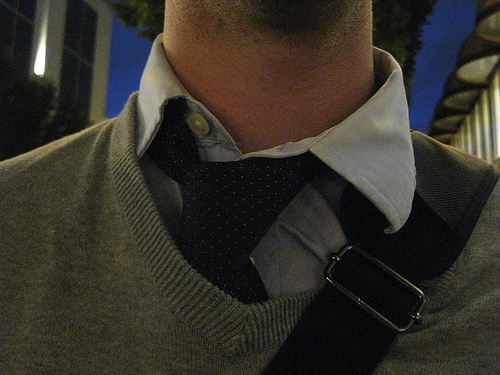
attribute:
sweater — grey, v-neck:
[0, 88, 499, 373]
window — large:
[54, 4, 99, 119]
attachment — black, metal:
[332, 244, 499, 318]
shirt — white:
[130, 27, 490, 276]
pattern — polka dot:
[186, 172, 263, 217]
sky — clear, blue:
[105, 14, 151, 122]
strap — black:
[259, 163, 499, 374]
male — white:
[0, 3, 498, 373]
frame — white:
[30, 3, 110, 129]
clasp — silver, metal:
[321, 241, 429, 336]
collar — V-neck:
[199, 266, 348, 361]